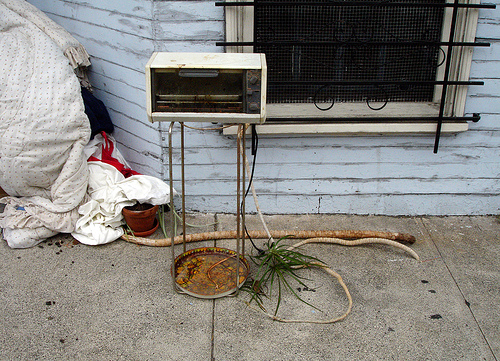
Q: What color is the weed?
A: Green.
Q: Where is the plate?
A: On the ground.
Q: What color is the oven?
A: White.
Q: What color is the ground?
A: Gray.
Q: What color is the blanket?
A: White.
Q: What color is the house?
A: Blue.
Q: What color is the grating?
A: Black.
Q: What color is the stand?
A: Gray.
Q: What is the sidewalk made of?
A: Cement.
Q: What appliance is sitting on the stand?
A: A toaster oven.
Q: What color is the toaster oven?
A: White.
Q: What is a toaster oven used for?
A: Cooking.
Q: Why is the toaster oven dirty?
A: It's been used.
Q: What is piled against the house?
A: Clothes.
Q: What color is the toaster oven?
A: White.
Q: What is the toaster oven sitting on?
A: A rusty stand.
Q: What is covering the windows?
A: Iron bars.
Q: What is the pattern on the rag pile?
A: Polka dots.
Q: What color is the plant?
A: Green.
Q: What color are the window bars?
A: Black.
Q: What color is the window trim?
A: White.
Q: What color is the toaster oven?
A: White.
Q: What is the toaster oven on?
A: A metal stand.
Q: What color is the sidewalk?
A: Gray.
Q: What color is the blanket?
A: White.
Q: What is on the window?
A: Metal bars.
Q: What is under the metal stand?
A: A metal tray.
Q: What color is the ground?
A: Gray.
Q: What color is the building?
A: Blue.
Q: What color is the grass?
A: Green.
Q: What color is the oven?
A: White.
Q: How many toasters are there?
A: One.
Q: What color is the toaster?
A: White and black.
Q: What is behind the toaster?
A: A window.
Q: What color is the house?
A: White.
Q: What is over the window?
A: Bars.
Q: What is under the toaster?
A: A stand.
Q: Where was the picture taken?
A: On the sidewalk.